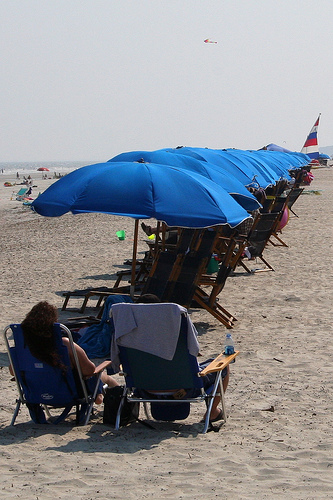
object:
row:
[26, 142, 312, 305]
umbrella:
[219, 148, 277, 187]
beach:
[0, 161, 331, 498]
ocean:
[0, 159, 107, 170]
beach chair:
[110, 302, 240, 434]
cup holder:
[222, 349, 236, 356]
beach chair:
[3, 322, 113, 427]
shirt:
[110, 301, 202, 374]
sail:
[299, 112, 322, 160]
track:
[42, 478, 90, 490]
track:
[163, 468, 202, 480]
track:
[250, 468, 288, 476]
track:
[254, 438, 298, 453]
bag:
[102, 384, 140, 426]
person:
[132, 293, 230, 425]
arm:
[198, 349, 240, 377]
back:
[110, 300, 206, 403]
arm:
[60, 336, 96, 375]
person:
[18, 299, 122, 404]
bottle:
[224, 334, 235, 363]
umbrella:
[37, 167, 50, 179]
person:
[142, 222, 179, 237]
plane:
[203, 38, 218, 45]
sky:
[24, 32, 320, 119]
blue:
[105, 171, 141, 201]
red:
[36, 167, 50, 172]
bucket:
[116, 230, 126, 241]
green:
[116, 230, 125, 238]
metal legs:
[202, 370, 227, 435]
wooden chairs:
[76, 293, 129, 359]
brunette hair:
[21, 300, 71, 374]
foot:
[140, 221, 152, 237]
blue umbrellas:
[30, 159, 252, 232]